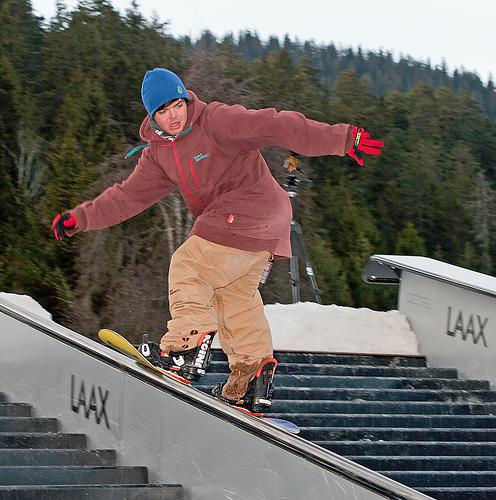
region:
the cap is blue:
[123, 65, 195, 118]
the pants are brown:
[143, 221, 284, 407]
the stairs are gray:
[296, 342, 454, 482]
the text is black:
[440, 294, 495, 361]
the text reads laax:
[440, 299, 495, 355]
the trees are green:
[46, 19, 115, 169]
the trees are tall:
[381, 57, 461, 253]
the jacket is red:
[71, 84, 363, 290]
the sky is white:
[360, 2, 466, 53]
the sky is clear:
[376, 0, 478, 72]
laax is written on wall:
[49, 368, 120, 423]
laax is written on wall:
[66, 371, 144, 443]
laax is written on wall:
[438, 288, 480, 346]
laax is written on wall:
[58, 323, 121, 440]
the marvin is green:
[91, 61, 203, 114]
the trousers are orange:
[151, 238, 285, 344]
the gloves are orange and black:
[36, 210, 86, 245]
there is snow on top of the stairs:
[275, 294, 387, 343]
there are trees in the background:
[318, 98, 493, 234]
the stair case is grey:
[312, 367, 464, 459]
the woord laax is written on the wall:
[44, 367, 129, 446]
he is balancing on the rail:
[70, 86, 318, 398]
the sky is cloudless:
[158, 8, 482, 46]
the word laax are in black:
[59, 378, 128, 426]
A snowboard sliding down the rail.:
[89, 323, 321, 427]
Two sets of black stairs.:
[1, 291, 494, 498]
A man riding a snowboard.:
[47, 50, 389, 419]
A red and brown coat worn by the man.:
[63, 88, 352, 270]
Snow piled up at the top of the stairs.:
[1, 283, 441, 365]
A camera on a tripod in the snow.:
[242, 115, 351, 318]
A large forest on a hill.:
[2, 10, 495, 339]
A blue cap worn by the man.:
[130, 62, 212, 136]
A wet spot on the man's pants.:
[147, 329, 278, 419]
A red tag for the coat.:
[214, 208, 247, 233]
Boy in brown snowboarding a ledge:
[49, 63, 385, 434]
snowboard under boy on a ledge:
[97, 325, 310, 434]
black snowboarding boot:
[212, 356, 277, 413]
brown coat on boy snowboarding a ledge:
[73, 91, 350, 259]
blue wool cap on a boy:
[140, 65, 186, 111]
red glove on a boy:
[347, 123, 386, 165]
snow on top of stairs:
[213, 299, 415, 354]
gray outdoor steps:
[166, 350, 494, 498]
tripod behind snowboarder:
[263, 162, 320, 305]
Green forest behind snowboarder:
[1, 0, 495, 311]